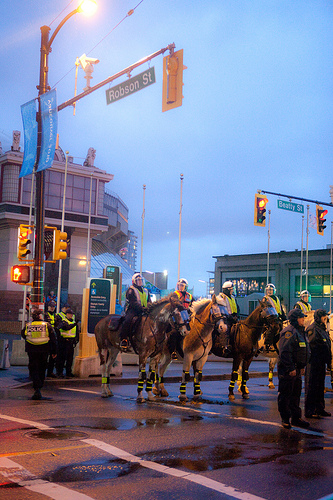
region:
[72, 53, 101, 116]
traffic camera on top of street light pole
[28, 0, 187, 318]
street light and traffic light pole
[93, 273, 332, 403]
policemen sitting on horses in street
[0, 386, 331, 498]
white painting on street marking pedestrians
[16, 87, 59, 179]
blue and white banner hanging off light pole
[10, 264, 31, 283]
electronic pedestrian signal on light pole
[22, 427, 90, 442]
metal man hole cover covering sewer system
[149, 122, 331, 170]
light blue partially clear sky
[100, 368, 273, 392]
bright neon green caution socks on horses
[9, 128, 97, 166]
gargoyles on either side of top of building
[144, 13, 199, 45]
white clouds in blue sky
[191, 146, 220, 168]
white clouds in blue sky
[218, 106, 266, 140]
white clouds in blue sky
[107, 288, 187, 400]
officer on horse back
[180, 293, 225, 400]
officer on horse back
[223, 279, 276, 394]
officer on horse back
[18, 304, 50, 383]
police officer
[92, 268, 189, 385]
police officer on horse back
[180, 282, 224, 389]
police officer on horse back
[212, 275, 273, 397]
police officer on horse back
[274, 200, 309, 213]
sign showing "beatty st"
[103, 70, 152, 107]
sign showing "robson st"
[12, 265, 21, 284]
lighted "don't walk" hand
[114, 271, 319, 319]
four police officers on horseback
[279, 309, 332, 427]
two men standing in front of officers on horseback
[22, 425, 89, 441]
manhole cover on street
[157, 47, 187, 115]
back of traffic light at top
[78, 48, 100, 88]
security camera on pole at top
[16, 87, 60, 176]
blue banners on lightpost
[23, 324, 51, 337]
"POLICE" on officer's back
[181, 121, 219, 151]
white clouds in blue sky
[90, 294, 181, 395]
horse ridden by officer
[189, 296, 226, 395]
horse ridden by officer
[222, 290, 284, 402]
horse ridden by officer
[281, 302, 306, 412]
standing police officer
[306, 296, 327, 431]
standing police officer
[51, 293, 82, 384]
standing male police officer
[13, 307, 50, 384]
standing male police officer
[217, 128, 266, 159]
white clouds in blue sky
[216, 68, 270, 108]
white clouds in blue sky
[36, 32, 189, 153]
a traffic signal.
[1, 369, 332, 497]
a white line cross walk.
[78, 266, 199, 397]
a cop on the back of a horse.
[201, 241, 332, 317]
a multi story building.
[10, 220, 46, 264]
a red traffic light.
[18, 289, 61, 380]
a cop on a sidewalk.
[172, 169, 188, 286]
a tall pole near a road.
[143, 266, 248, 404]
a cop riding a brown horse.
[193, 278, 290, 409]
a dark horse with a rider.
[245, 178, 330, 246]
a traffic signal.